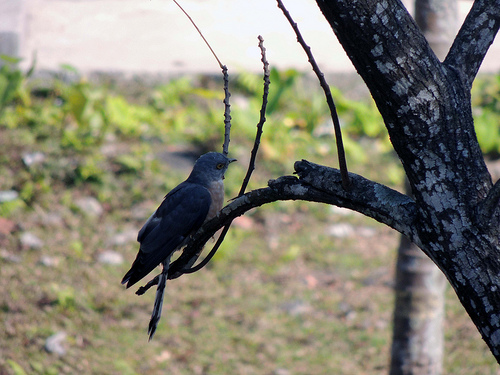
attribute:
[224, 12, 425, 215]
branch — white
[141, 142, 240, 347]
bird — blue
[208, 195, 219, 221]
chest — white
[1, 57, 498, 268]
weeds — green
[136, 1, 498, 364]
tree — black, grey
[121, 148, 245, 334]
bird — small, blue and white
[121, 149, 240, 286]
bird — blue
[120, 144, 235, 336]
bird — dark grey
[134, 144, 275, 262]
bird — blue gray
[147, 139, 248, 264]
bird — blue and white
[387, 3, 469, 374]
tree trunk — thin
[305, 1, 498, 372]
tree trunk — light grey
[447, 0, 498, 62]
limb — small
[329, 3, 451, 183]
limb — dark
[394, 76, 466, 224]
splotches — white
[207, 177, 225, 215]
chest — white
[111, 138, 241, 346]
bird — blue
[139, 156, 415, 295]
limb — dead